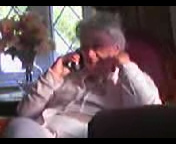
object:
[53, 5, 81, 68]
glass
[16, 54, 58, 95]
glass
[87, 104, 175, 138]
arm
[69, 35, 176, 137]
chair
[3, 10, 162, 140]
woman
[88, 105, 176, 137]
dark object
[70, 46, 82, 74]
roof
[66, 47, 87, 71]
cellphone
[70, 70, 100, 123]
shirt strings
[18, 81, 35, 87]
rocks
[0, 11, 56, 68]
flowers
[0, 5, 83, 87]
windows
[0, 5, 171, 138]
scene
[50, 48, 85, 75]
hand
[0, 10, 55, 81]
bouquet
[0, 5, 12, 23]
pane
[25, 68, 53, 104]
wrinkles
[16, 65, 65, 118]
sleeve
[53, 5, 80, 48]
pattern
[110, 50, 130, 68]
hand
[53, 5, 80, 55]
pane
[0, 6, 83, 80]
window glass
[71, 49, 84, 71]
phone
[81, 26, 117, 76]
face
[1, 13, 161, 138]
man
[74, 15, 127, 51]
hair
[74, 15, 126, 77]
head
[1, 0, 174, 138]
wall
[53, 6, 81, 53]
diamond shape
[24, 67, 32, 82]
stem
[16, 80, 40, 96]
vase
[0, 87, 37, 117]
table